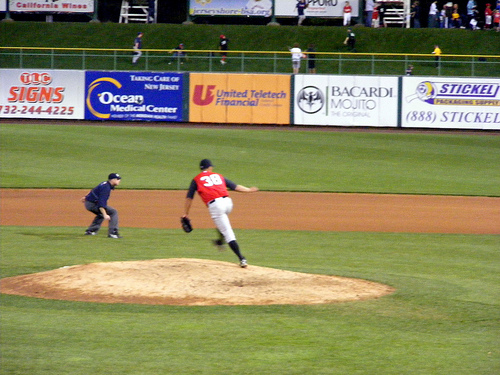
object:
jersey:
[186, 171, 238, 205]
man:
[432, 46, 443, 67]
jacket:
[433, 47, 442, 54]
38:
[199, 173, 222, 187]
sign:
[400, 76, 500, 130]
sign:
[189, 72, 291, 125]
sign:
[85, 71, 184, 123]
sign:
[0, 67, 85, 119]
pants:
[207, 196, 237, 243]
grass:
[435, 320, 499, 358]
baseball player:
[179, 158, 260, 268]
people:
[289, 43, 307, 74]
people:
[343, 28, 356, 49]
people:
[218, 34, 230, 64]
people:
[132, 32, 145, 64]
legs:
[206, 197, 248, 267]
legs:
[84, 201, 105, 236]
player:
[81, 173, 124, 239]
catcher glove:
[180, 216, 194, 233]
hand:
[181, 179, 198, 219]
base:
[109, 259, 146, 281]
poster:
[289, 74, 399, 128]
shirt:
[84, 181, 114, 215]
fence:
[0, 45, 87, 69]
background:
[0, 0, 117, 40]